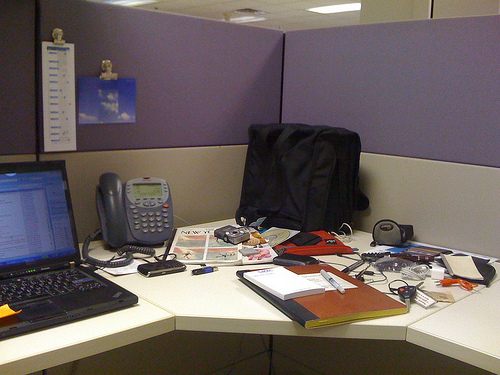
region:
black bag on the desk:
[233, 120, 368, 240]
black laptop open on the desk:
[0, 161, 125, 327]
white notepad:
[240, 256, 315, 306]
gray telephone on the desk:
[93, 170, 179, 265]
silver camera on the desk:
[212, 215, 242, 245]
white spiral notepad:
[440, 247, 480, 274]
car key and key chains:
[390, 280, 450, 305]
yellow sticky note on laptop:
[0, 300, 20, 325]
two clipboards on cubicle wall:
[36, 16, 127, 161]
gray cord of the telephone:
[80, 236, 131, 267]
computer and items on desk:
[1, 50, 496, 370]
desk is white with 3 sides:
[14, 113, 470, 371]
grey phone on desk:
[66, 148, 210, 276]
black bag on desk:
[193, 71, 403, 316]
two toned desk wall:
[10, 19, 498, 275]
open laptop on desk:
[0, 140, 170, 372]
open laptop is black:
[217, 103, 395, 258]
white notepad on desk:
[220, 241, 345, 317]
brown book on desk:
[221, 246, 416, 338]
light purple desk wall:
[10, 0, 471, 175]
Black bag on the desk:
[227, 109, 365, 234]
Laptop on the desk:
[1, 148, 142, 343]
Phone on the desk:
[71, 165, 179, 267]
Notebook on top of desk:
[236, 251, 411, 341]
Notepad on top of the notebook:
[241, 248, 328, 308]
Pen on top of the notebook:
[312, 259, 349, 300]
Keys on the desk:
[382, 272, 458, 318]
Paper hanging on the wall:
[35, 21, 83, 155]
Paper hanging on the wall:
[75, 58, 143, 136]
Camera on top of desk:
[212, 216, 256, 253]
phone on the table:
[102, 165, 174, 255]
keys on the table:
[380, 277, 425, 305]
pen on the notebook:
[308, 253, 340, 299]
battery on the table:
[187, 261, 217, 284]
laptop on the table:
[1, 148, 121, 325]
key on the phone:
[140, 225, 153, 239]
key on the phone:
[164, 225, 170, 231]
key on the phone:
[143, 210, 152, 217]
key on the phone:
[131, 218, 138, 227]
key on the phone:
[155, 200, 167, 207]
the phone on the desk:
[86, 161, 184, 269]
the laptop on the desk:
[0, 158, 134, 331]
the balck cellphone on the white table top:
[137, 251, 189, 279]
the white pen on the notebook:
[320, 263, 349, 298]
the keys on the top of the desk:
[389, 273, 445, 312]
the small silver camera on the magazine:
[215, 216, 247, 248]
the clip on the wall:
[95, 58, 124, 80]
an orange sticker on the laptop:
[0, 303, 24, 325]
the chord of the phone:
[79, 235, 156, 268]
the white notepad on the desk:
[244, 264, 326, 300]